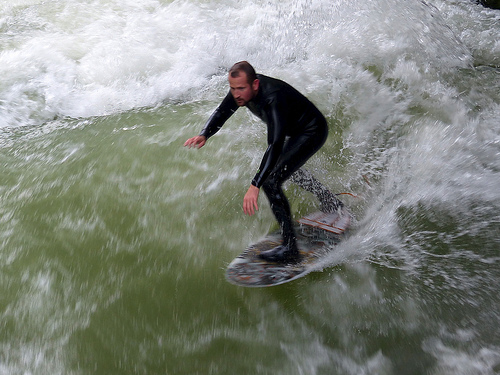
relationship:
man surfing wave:
[201, 56, 355, 255] [82, 29, 306, 70]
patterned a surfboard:
[307, 217, 337, 248] [226, 210, 305, 328]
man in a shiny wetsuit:
[201, 56, 355, 255] [265, 85, 312, 156]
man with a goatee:
[201, 56, 355, 255] [234, 94, 249, 106]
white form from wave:
[65, 13, 220, 67] [328, 51, 449, 186]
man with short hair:
[201, 56, 355, 255] [224, 58, 251, 87]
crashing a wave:
[65, 13, 220, 67] [328, 51, 449, 186]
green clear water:
[77, 124, 191, 241] [68, 22, 154, 54]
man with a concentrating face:
[201, 56, 355, 255] [228, 77, 251, 106]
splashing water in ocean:
[374, 111, 469, 234] [35, 22, 191, 237]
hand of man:
[241, 186, 260, 216] [188, 56, 334, 262]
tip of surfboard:
[216, 263, 264, 291] [226, 210, 305, 328]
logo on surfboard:
[306, 218, 332, 243] [226, 210, 305, 328]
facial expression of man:
[222, 68, 254, 112] [188, 56, 334, 262]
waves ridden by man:
[328, 51, 449, 186] [188, 56, 334, 262]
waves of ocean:
[215, 20, 340, 55] [35, 22, 191, 237]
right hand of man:
[178, 129, 215, 156] [188, 56, 334, 262]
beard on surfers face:
[234, 94, 249, 106] [216, 68, 275, 121]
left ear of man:
[252, 77, 262, 90] [188, 56, 334, 262]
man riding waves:
[188, 56, 334, 262] [215, 20, 340, 55]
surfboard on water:
[226, 210, 305, 328] [68, 22, 154, 54]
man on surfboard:
[201, 56, 355, 255] [226, 210, 305, 328]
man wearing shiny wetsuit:
[201, 56, 355, 255] [201, 76, 347, 261]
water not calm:
[68, 22, 154, 54] [343, 8, 482, 119]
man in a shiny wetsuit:
[201, 56, 355, 255] [201, 76, 347, 261]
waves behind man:
[215, 20, 340, 55] [188, 56, 334, 262]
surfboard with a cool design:
[226, 210, 305, 328] [253, 230, 318, 273]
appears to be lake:
[9, 10, 71, 86] [13, 284, 109, 361]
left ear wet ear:
[253, 78, 260, 91] [252, 77, 262, 90]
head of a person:
[217, 56, 264, 112] [201, 56, 355, 255]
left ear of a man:
[252, 77, 262, 90] [188, 56, 334, 262]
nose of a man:
[230, 90, 242, 100] [188, 56, 334, 262]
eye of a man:
[228, 86, 254, 96] [188, 56, 334, 262]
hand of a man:
[184, 133, 270, 218] [188, 56, 334, 262]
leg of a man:
[260, 169, 302, 268] [188, 56, 334, 262]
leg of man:
[260, 169, 302, 268] [188, 56, 334, 262]